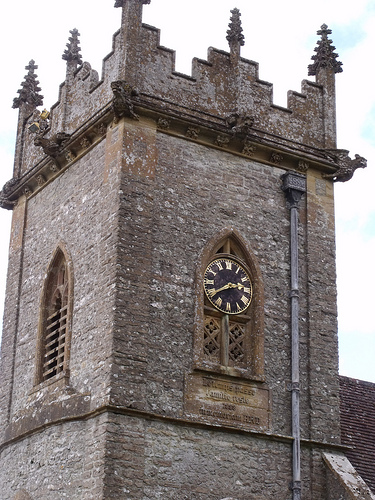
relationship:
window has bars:
[35, 240, 70, 383] [44, 305, 63, 375]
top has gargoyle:
[0, 0, 373, 207] [32, 134, 69, 157]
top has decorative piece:
[0, 0, 373, 207] [109, 78, 139, 124]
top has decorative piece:
[0, 0, 373, 207] [226, 111, 256, 142]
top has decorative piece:
[0, 0, 373, 207] [321, 148, 367, 183]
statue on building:
[202, 0, 250, 58] [300, 123, 363, 178]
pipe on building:
[286, 196, 302, 498] [283, 198, 307, 480]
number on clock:
[222, 261, 232, 271] [204, 252, 254, 314]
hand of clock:
[208, 285, 228, 296] [195, 251, 258, 311]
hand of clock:
[207, 281, 228, 291] [195, 251, 258, 311]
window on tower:
[35, 240, 70, 383] [1, 4, 373, 495]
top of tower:
[0, 0, 373, 207] [1, 4, 373, 495]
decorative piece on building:
[321, 148, 367, 183] [0, 0, 371, 496]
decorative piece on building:
[226, 111, 256, 142] [0, 0, 371, 496]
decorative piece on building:
[109, 78, 139, 124] [0, 0, 371, 496]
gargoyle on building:
[32, 134, 69, 157] [0, 0, 371, 496]